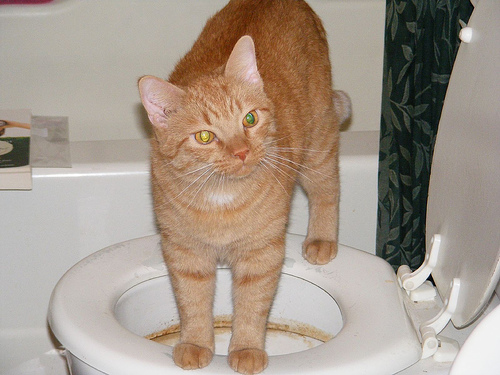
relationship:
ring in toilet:
[140, 313, 334, 353] [44, 225, 492, 372]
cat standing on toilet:
[132, 0, 346, 372] [40, 4, 494, 373]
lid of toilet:
[415, 3, 499, 324] [40, 4, 494, 373]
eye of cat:
[188, 124, 217, 147] [132, 0, 346, 372]